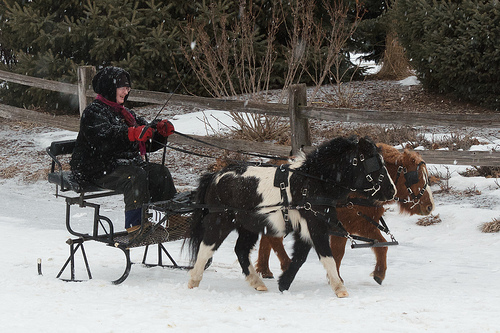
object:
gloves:
[127, 124, 155, 142]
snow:
[414, 242, 481, 291]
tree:
[198, 0, 392, 94]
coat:
[69, 98, 173, 182]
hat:
[93, 66, 133, 102]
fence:
[0, 64, 500, 172]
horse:
[256, 139, 436, 277]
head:
[378, 148, 437, 217]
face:
[115, 83, 129, 104]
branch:
[200, 3, 225, 94]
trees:
[2, 0, 161, 116]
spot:
[254, 176, 309, 239]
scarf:
[91, 95, 154, 157]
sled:
[53, 198, 199, 283]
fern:
[399, 11, 500, 111]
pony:
[274, 142, 448, 225]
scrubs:
[185, 4, 361, 126]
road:
[0, 187, 492, 330]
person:
[69, 67, 180, 233]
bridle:
[283, 142, 381, 199]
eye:
[363, 150, 375, 158]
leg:
[187, 215, 224, 290]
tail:
[176, 173, 217, 269]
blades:
[111, 248, 134, 284]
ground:
[0, 172, 500, 333]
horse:
[178, 135, 395, 299]